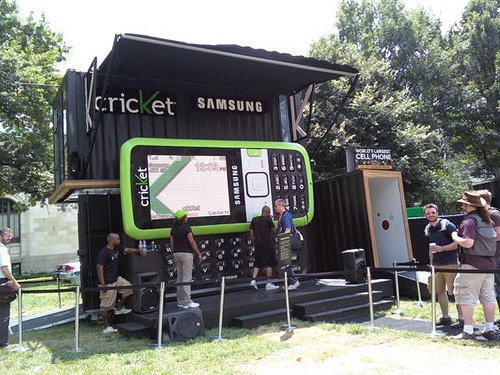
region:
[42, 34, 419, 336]
a portable stage is for advertisement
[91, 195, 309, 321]
people are standing on the stage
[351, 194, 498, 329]
a line is waiting to go on the stage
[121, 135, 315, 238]
an enlarged cell phone is on the stage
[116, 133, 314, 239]
the cell phone is green and black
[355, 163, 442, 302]
a ramp leads into a doorway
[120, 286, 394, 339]
steps leading to a black stage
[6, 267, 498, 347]
a fence is around the stage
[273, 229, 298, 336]
a sign is in front of the stage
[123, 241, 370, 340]
speakers are on and near the stage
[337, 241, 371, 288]
black speaker on platform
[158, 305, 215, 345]
black speaker on ground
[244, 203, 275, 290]
man on platform wearing black clothes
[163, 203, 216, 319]
woman on platform wearing green bandana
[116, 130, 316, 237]
large cell phone on platform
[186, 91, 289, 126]
large hanging logo sign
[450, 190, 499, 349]
man wearing cowboy hat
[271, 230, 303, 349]
black sign on ground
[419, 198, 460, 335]
man wearing blue shirt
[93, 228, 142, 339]
man wearing black shirt and khaki pants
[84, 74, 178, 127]
A sign that says Cricket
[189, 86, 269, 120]
A sign that says Samsung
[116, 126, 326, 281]
A giant cell phone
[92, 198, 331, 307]
People standing by a giant cell phone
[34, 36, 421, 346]
A black stage with a giant cell phone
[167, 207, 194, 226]
a woman wearing a green hat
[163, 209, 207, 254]
a woman wearing a black shirt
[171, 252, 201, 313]
a woman wearing tan pants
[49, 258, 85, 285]
the back end of a car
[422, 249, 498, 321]
two men wearing shorts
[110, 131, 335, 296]
a large phone model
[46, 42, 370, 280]
a black phone shop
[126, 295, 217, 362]
a black speaker box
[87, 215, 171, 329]
the man is standing next to the speaker box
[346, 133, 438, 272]
a black telephone booth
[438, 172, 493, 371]
the man has a backpack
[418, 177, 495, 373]
the men are wearing shorts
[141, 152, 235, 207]
the screen of a phone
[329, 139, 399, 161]
a black and white display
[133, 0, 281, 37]
the sky is white in colour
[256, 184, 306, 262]
this is a man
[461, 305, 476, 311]
the man is light skinned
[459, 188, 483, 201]
this is a hat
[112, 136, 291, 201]
this is a phone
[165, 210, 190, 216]
this is a cap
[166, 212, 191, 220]
the cap is green in color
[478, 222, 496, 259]
this is a bag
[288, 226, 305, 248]
the bag is black in color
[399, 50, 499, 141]
this is a tree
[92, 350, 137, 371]
this is a grass area